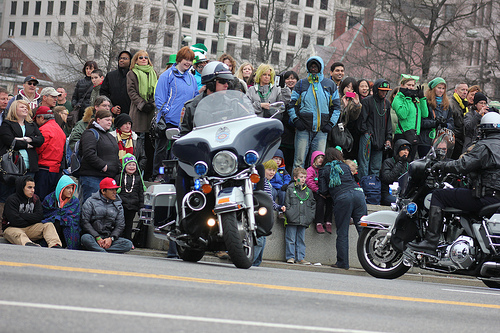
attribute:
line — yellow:
[2, 260, 499, 309]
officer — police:
[196, 63, 248, 129]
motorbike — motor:
[353, 144, 498, 289]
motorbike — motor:
[158, 87, 287, 271]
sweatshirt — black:
[3, 173, 45, 227]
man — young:
[357, 76, 393, 182]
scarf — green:
[130, 53, 178, 107]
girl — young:
[388, 69, 428, 146]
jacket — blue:
[392, 96, 429, 132]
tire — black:
[220, 211, 253, 268]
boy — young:
[284, 167, 315, 264]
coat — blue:
[155, 69, 197, 129]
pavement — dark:
[2, 242, 499, 332]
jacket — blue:
[152, 65, 197, 125]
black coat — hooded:
[97, 48, 129, 94]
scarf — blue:
[165, 50, 255, 98]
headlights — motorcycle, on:
[250, 150, 258, 188]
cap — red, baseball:
[96, 175, 122, 190]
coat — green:
[393, 89, 430, 136]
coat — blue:
[286, 55, 342, 145]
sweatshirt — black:
[362, 95, 391, 147]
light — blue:
[242, 149, 257, 166]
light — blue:
[190, 159, 209, 177]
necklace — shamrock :
[117, 179, 141, 205]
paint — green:
[294, 176, 301, 186]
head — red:
[175, 44, 196, 71]